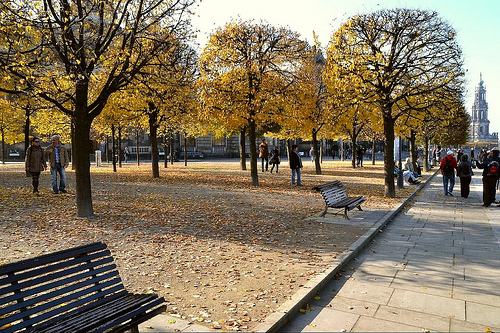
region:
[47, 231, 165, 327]
a black painted bench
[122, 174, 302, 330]
yellow and brown leaves on ground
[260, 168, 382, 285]
bench on a concrete base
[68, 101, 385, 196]
tall trees with yellow leaves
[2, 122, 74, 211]
two people walking together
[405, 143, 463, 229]
person with a black back pack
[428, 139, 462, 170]
person wearing a white hat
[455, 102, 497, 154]
a tall white building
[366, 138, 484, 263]
people walking on the street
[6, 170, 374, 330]
two benches in park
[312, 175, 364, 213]
a brown wooden bench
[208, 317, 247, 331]
a group of leaves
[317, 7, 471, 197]
a tall tree with fall colored leaves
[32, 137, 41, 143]
dark black sunglasses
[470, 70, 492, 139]
the top of a building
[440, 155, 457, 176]
a black backpack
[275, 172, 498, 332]
a concrete walkway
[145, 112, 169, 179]
the trunk of a tree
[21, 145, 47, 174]
a woman's brown jacket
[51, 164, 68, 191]
a man's blue jean pants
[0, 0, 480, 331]
a small park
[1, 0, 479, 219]
tall trees with golden leaves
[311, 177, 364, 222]
a park bench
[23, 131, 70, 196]
a couple walking through the park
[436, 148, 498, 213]
a group of people walking on the sidewalk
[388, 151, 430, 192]
a group of people sitting down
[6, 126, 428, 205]
people in the park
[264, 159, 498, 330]
a concrete sidewalk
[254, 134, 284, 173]
a man and young girl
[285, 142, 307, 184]
a man wearing a black jacket in the park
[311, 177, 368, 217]
black park bench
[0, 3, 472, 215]
trees with yellow leaves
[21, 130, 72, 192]
couple walking through trees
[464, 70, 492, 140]
tall building down path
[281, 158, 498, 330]
stone path in the park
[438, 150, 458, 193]
man with red shirt and black backpack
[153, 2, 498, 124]
bright white and blue sky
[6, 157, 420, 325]
ground covered in leaves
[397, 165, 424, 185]
person sittin gunder tree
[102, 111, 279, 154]
buildings behind trees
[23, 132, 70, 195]
a husband and wife walking across a public park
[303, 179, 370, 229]
a bench on the side of the park near the sidewalk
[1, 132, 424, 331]
people in a public park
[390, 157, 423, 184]
two people sitting on a park bench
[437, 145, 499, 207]
people walking on the sidewalk beside the park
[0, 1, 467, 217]
trees in the park during the fall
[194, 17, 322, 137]
yellow leaves on the tree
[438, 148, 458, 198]
man in a white hat carrying a backpack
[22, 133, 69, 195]
a couple taking stroll in the park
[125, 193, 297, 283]
leaves on the park's ground